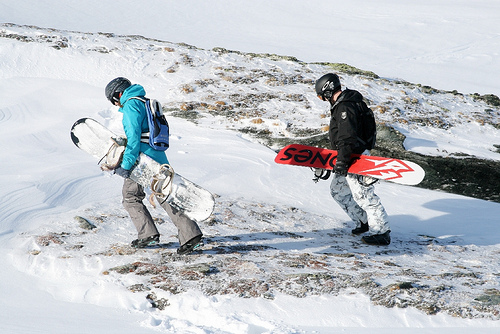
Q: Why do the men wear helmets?
A: Protection.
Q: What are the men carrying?
A: Snowboards.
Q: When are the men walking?
A: Daytime.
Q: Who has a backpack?
A: The man in front.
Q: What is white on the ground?
A: Snow.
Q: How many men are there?
A: Two.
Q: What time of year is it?
A: Winter.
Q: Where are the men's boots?
A: On their feet.